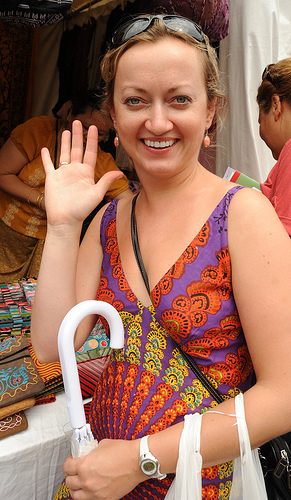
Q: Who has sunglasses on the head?
A: A woman.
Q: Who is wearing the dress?
A: A woman.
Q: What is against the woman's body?
A: The strap of a black purse.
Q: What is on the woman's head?
A: Sunglasses.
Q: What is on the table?
A: Fabric swatches.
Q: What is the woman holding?
A: White umbrella.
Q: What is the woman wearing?
A: A purple, red and black dress.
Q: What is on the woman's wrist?
A: A watch.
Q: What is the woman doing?
A: Waving.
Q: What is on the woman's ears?
A: Earrings.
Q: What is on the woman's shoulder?
A: Handbag strap,.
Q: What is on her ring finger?
A: A ring.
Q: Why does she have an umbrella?
A: It is a sunny day.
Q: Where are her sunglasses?
A: On her head.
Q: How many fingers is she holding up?
A: Five.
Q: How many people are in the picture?
A: Three.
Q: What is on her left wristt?
A: A watch.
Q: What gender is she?
A: Female.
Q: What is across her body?
A: A purse.